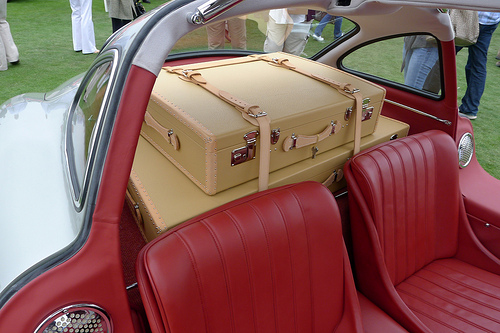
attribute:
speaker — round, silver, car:
[31, 300, 113, 331]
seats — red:
[147, 170, 482, 331]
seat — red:
[141, 180, 378, 332]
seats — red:
[131, 124, 499, 331]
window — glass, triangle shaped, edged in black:
[339, 34, 441, 95]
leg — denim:
[402, 42, 441, 93]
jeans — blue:
[403, 46, 442, 88]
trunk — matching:
[0, 22, 463, 218]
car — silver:
[2, 3, 151, 281]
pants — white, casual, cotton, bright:
[68, 0, 98, 57]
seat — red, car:
[133, 178, 365, 331]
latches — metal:
[232, 132, 257, 163]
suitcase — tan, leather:
[139, 49, 387, 196]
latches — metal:
[360, 102, 373, 121]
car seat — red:
[349, 112, 498, 327]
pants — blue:
[460, 20, 498, 117]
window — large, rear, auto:
[102, 10, 354, 77]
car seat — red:
[133, 180, 364, 332]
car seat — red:
[341, 127, 498, 331]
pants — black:
[463, 7, 498, 112]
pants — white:
[69, 1, 94, 54]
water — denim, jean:
[404, 42, 442, 92]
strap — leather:
[251, 106, 275, 176]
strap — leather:
[349, 86, 369, 151]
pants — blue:
[406, 43, 440, 89]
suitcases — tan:
[153, 73, 361, 186]